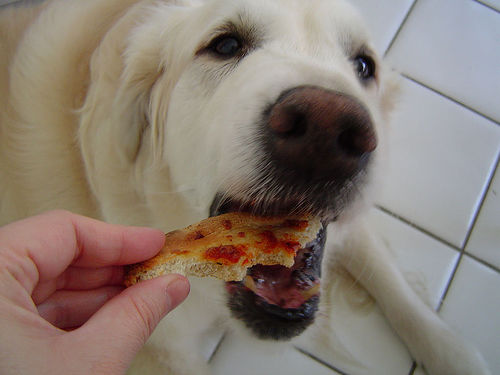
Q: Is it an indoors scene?
A: Yes, it is indoors.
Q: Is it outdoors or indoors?
A: It is indoors.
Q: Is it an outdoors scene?
A: No, it is indoors.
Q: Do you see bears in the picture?
A: No, there are no bears.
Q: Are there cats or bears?
A: No, there are no bears or cats.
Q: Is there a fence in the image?
A: No, there are no fences.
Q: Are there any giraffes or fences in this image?
A: No, there are no fences or giraffes.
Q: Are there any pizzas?
A: Yes, there is a pizza.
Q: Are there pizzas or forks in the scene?
A: Yes, there is a pizza.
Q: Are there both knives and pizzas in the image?
A: No, there is a pizza but no knives.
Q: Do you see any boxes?
A: No, there are no boxes.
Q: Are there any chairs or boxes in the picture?
A: No, there are no boxes or chairs.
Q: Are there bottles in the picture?
A: No, there are no bottles.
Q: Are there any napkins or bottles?
A: No, there are no bottles or napkins.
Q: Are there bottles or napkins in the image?
A: No, there are no bottles or napkins.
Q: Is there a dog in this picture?
A: Yes, there is a dog.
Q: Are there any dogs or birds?
A: Yes, there is a dog.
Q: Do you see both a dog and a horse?
A: No, there is a dog but no horses.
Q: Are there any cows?
A: No, there are no cows.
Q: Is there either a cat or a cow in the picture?
A: No, there are no cows or cats.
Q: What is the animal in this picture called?
A: The animal is a dog.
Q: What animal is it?
A: The animal is a dog.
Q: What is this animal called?
A: That is a dog.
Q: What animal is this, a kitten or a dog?
A: That is a dog.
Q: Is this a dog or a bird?
A: This is a dog.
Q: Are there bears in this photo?
A: No, there are no bears.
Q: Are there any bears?
A: No, there are no bears.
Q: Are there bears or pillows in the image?
A: No, there are no bears or pillows.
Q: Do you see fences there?
A: No, there are no fences.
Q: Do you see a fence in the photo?
A: No, there are no fences.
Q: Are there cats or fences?
A: No, there are no fences or cats.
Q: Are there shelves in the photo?
A: No, there are no shelves.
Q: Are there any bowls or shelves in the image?
A: No, there are no shelves or bowls.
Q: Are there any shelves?
A: No, there are no shelves.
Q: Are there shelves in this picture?
A: No, there are no shelves.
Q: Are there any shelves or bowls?
A: No, there are no shelves or bowls.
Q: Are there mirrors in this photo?
A: No, there are no mirrors.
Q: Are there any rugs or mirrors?
A: No, there are no mirrors or rugs.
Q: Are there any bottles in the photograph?
A: No, there are no bottles.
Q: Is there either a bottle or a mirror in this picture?
A: No, there are no bottles or mirrors.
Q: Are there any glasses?
A: No, there are no glasses.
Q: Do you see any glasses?
A: No, there are no glasses.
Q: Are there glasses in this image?
A: No, there are no glasses.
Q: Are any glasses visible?
A: No, there are no glasses.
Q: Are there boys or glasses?
A: No, there are no glasses or boys.